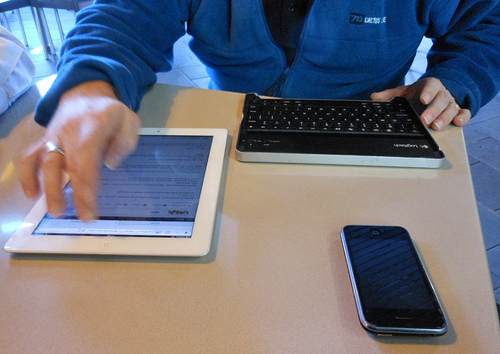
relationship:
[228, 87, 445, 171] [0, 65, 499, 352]
keyboard on table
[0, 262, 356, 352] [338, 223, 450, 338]
table top with cellphone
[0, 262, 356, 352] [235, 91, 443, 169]
table top with keyboard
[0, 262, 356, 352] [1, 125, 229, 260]
table top with ipad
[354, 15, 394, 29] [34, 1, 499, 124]
logo on blue jacket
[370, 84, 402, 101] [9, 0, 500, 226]
thumb on a man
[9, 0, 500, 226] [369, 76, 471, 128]
man left hand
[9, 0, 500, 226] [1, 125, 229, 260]
man using a ipad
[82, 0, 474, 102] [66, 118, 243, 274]
man typing on tablet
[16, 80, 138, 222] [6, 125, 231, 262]
hand touching ipad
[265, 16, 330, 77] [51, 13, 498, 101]
zipper on jacket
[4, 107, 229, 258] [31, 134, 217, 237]
ipad displaying a web browser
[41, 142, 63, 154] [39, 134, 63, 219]
ring on persons finger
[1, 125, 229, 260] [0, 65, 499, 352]
ipad on table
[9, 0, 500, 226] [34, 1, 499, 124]
man wearing a blue jacket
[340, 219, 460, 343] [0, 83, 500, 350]
cellphone on a desk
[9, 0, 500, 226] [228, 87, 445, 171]
man touching a keyboard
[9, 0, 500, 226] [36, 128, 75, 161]
man wearing an engagement ring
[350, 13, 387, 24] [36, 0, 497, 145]
logo on a sweater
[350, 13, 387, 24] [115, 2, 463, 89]
logo on a shirt